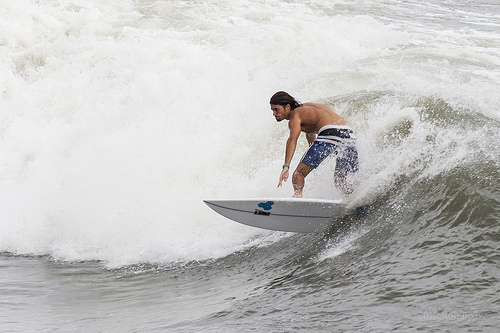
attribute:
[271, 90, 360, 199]
surfer — surfing, at the beach, turned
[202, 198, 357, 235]
surf board — white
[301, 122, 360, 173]
shorts — blue, white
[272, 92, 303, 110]
hair — wet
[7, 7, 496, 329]
water — white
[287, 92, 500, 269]
wave — gray, white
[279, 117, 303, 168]
arm — extended